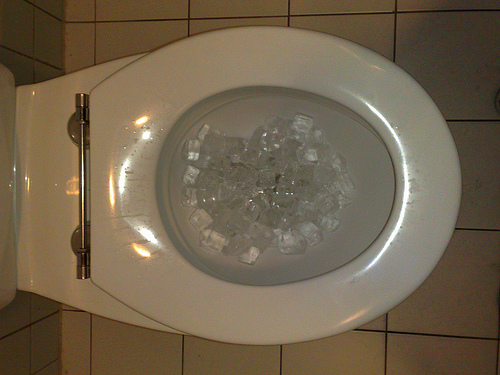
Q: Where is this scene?
A: Bathroom.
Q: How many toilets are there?
A: One.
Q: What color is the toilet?
A: White.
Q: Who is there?
A: No one.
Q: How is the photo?
A: Clear.